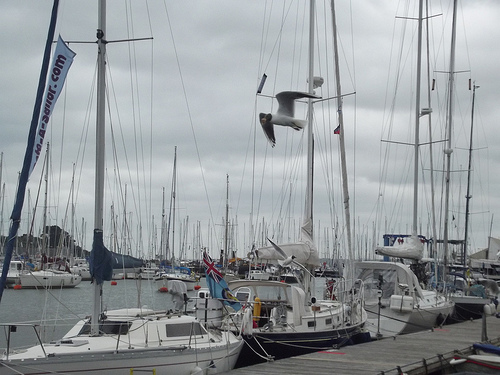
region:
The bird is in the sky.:
[259, 87, 312, 149]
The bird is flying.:
[260, 78, 321, 148]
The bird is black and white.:
[251, 91, 326, 146]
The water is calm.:
[18, 288, 75, 315]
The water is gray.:
[11, 294, 76, 316]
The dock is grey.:
[363, 343, 398, 365]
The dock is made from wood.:
[362, 344, 401, 361]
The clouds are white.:
[198, 23, 255, 65]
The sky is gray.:
[206, 71, 250, 111]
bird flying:
[245, 83, 322, 143]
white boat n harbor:
[17, 295, 223, 370]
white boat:
[219, 257, 351, 342]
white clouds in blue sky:
[159, 53, 191, 89]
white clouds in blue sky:
[129, 118, 166, 143]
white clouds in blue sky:
[206, 180, 246, 210]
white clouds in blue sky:
[347, 17, 409, 74]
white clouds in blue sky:
[359, 68, 376, 156]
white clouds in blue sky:
[429, 30, 491, 65]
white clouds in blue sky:
[131, 23, 174, 68]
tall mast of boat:
[80, 27, 123, 330]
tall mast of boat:
[302, 15, 324, 285]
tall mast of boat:
[407, 43, 419, 271]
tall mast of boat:
[446, 42, 458, 284]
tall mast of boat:
[159, 152, 179, 271]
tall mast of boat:
[39, 161, 61, 277]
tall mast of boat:
[216, 157, 241, 267]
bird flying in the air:
[240, 80, 315, 152]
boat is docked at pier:
[23, 300, 228, 374]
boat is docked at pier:
[245, 278, 369, 356]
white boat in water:
[12, 289, 254, 370]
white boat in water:
[241, 279, 441, 341]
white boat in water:
[22, 246, 86, 313]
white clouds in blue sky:
[154, 22, 205, 62]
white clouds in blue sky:
[141, 111, 181, 155]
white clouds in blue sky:
[181, 125, 212, 179]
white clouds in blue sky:
[357, 76, 399, 136]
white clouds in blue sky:
[377, 125, 419, 176]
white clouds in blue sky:
[122, 22, 179, 93]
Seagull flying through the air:
[259, 88, 319, 144]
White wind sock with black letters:
[28, 37, 77, 179]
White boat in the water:
[6, 305, 241, 366]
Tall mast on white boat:
[91, 0, 104, 337]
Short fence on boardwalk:
[372, 338, 472, 373]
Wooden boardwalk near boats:
[235, 318, 497, 373]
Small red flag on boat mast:
[334, 125, 341, 133]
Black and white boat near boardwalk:
[197, 283, 379, 348]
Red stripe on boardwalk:
[318, 348, 347, 355]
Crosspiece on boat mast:
[52, 38, 156, 45]